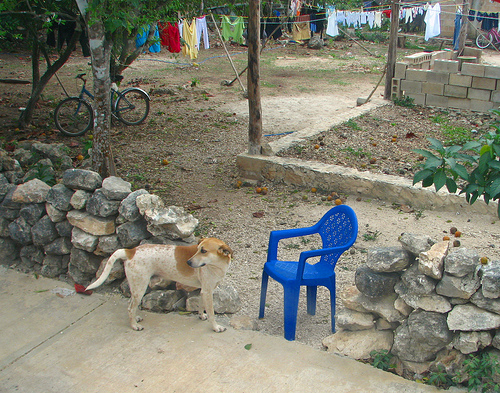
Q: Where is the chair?
A: On the dirt.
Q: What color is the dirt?
A: Brown.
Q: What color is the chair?
A: Blue.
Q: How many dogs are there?
A: One.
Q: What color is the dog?
A: Brown and white.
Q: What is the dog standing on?
A: The sidewalk.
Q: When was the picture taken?
A: Daytime.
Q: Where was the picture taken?
A: In a yard.